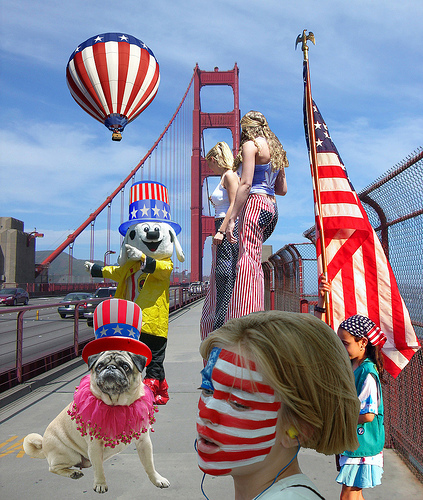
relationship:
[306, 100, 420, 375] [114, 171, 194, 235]
flag on hat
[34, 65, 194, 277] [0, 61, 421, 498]
pole by bridge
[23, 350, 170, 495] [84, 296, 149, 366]
dog wearing hat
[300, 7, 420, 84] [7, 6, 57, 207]
clouds in sky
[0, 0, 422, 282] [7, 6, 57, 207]
clouds in sky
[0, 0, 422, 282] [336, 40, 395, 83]
clouds in sky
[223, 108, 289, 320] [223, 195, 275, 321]
woman wearing pants